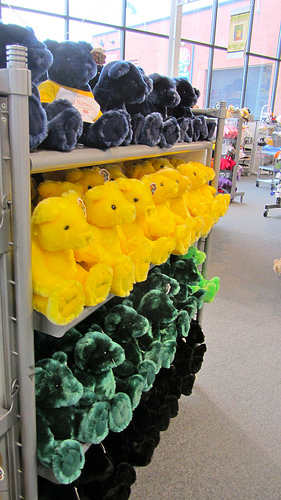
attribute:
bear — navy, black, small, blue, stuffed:
[37, 38, 127, 147]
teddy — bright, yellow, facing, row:
[81, 182, 150, 300]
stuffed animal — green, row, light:
[102, 300, 156, 403]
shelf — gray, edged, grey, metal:
[0, 40, 215, 499]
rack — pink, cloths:
[216, 105, 254, 210]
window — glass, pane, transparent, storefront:
[171, 43, 211, 108]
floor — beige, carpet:
[132, 170, 277, 500]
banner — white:
[224, 6, 255, 55]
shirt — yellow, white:
[37, 79, 105, 123]